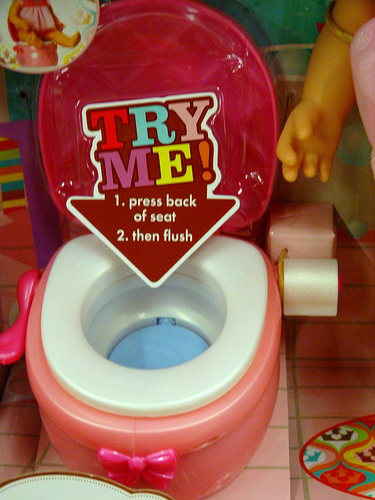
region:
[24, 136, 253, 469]
Toy toilet bowl on shelf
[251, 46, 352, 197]
Doll arm next to toilet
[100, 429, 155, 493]
Pink bow on the toilet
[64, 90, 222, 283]
Try me sign on the toilet bowl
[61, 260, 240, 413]
White toilet seat on the bowl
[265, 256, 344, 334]
Plastic paper toilet roll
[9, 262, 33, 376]
Pink handle on toilet bowl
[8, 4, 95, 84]
Bear picture on toilet bowl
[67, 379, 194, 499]
Pink bow on toilet bowl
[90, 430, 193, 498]
Pink bow on toilet bowl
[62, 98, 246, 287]
A sign with an arrow on it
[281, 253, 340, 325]
A small roll of toilet paper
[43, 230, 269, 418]
A white toilet seat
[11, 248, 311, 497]
A pink toilet bowl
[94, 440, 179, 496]
A pink plastic bow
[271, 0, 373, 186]
A doll arm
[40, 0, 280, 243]
A red toilet seat lid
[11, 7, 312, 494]
A childs potty training toilet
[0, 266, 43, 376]
A pink toilet handle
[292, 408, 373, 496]
Part of a bathroom rug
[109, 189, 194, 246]
white lettering on a brown tag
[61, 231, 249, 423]
a white plastic toilet seat and basin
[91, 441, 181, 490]
a plastic pink bow on the front of the toilet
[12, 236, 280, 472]
a plastic pink toy toilet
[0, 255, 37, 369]
pink plastic lever of the toilet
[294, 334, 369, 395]
striped pink cardboard of the box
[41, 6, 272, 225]
plastic pink toilet lid of the toy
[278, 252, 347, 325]
fake toilet paper mounted on the toy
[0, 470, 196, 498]
white front of the box with brown trim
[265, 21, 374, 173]
yellow arm of a doll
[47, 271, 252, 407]
this is a toilet sink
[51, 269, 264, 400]
the sink is open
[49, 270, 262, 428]
the toilet sink is plastic like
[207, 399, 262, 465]
the sink is pink in color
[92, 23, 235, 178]
the lid is red in color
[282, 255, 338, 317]
this is a tissue paper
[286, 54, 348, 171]
this is a hand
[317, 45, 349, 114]
the hand is toy like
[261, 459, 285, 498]
the floor is tiled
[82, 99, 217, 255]
this is an arrow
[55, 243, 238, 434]
white seat on toilet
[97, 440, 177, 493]
pink bow on toilet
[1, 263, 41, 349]
pink handle on toilet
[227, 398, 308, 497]
pink base under toilet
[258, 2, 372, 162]
orange hand on doll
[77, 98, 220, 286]
red arrow on demonstration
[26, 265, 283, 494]
light pink toilet for doll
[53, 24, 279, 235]
dark pink toilet lid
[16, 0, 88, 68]
picture for doll demonstration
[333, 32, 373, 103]
pink dress for doll